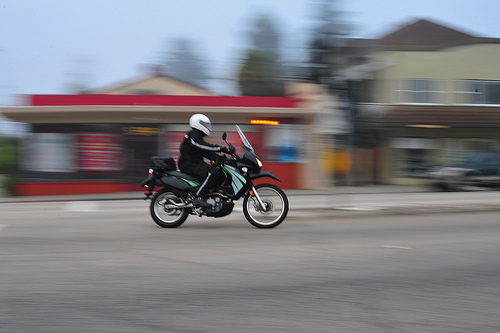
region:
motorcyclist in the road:
[134, 102, 294, 224]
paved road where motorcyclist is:
[13, 219, 488, 326]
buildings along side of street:
[44, 70, 497, 181]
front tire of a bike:
[248, 175, 288, 237]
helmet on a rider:
[187, 110, 218, 141]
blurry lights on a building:
[249, 115, 283, 131]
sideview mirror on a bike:
[216, 130, 232, 146]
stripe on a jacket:
[188, 138, 226, 154]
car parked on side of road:
[434, 152, 498, 189]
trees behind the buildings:
[233, 15, 295, 107]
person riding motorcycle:
[97, 65, 352, 279]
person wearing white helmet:
[142, 96, 250, 164]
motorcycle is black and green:
[126, 106, 296, 236]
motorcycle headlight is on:
[137, 92, 309, 244]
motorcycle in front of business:
[14, 62, 356, 277]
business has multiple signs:
[1, 44, 312, 242]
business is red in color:
[5, 68, 302, 225]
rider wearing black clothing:
[162, 97, 237, 227]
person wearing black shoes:
[178, 165, 226, 228]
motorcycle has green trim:
[126, 132, 295, 240]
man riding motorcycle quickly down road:
[131, 105, 304, 249]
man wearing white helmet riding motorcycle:
[134, 100, 328, 252]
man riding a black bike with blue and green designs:
[144, 109, 301, 238]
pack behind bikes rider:
[136, 141, 184, 186]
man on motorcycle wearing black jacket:
[146, 118, 303, 256]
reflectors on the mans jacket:
[179, 131, 227, 153]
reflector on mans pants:
[192, 167, 219, 209]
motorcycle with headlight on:
[249, 148, 274, 173]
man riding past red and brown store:
[0, 96, 320, 205]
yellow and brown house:
[331, 11, 492, 187]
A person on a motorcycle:
[139, 111, 291, 229]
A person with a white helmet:
[185, 110, 212, 136]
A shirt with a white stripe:
[177, 127, 220, 163]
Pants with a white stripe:
[177, 158, 219, 198]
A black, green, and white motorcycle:
[140, 124, 291, 230]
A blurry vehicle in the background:
[423, 148, 498, 193]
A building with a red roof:
[22, 91, 312, 106]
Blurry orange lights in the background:
[248, 116, 278, 125]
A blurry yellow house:
[365, 38, 499, 185]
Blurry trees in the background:
[1, 0, 363, 185]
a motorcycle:
[136, 166, 290, 230]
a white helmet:
[185, 115, 210, 126]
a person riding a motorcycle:
[176, 130, 233, 190]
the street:
[285, 235, 445, 325]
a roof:
[386, 22, 441, 42]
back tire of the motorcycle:
[148, 189, 189, 226]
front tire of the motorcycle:
[248, 181, 293, 226]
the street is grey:
[95, 233, 371, 318]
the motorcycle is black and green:
[160, 160, 287, 216]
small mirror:
[219, 128, 230, 144]